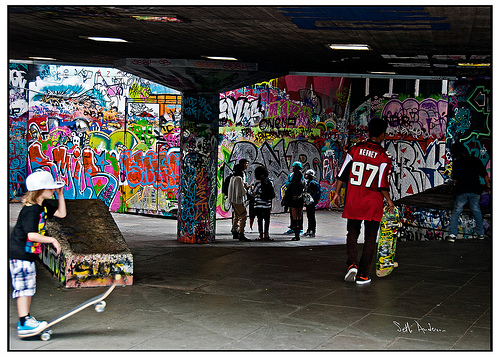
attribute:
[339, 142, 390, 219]
shirt — red, white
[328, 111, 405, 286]
man — white, walking, tall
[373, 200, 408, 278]
board — yellow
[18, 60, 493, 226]
wall — colorful, green, red, blue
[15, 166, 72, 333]
boy — white, standing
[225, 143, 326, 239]
people — standing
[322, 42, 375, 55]
light — white, on